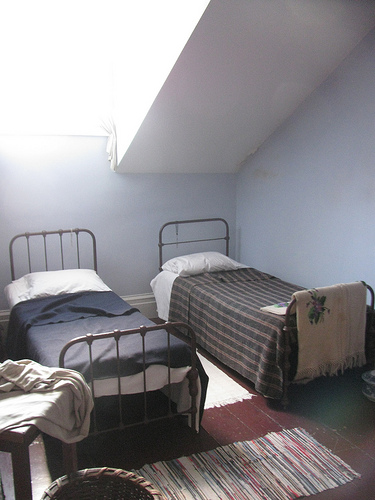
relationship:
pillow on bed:
[160, 250, 239, 275] [148, 218, 374, 412]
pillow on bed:
[12, 268, 110, 302] [148, 218, 374, 412]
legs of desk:
[4, 427, 63, 499] [0, 362, 76, 497]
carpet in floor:
[128, 426, 362, 500] [234, 400, 361, 450]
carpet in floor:
[128, 426, 362, 500] [207, 389, 374, 498]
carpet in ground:
[128, 426, 362, 500] [290, 400, 371, 463]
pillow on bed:
[12, 268, 110, 302] [8, 229, 198, 435]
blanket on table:
[0, 358, 94, 445] [2, 364, 90, 467]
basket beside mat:
[34, 461, 165, 499] [116, 423, 361, 495]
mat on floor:
[129, 426, 361, 498] [82, 361, 370, 498]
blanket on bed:
[260, 280, 367, 384] [147, 212, 372, 389]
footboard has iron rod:
[55, 309, 203, 419] [81, 339, 100, 437]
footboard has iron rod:
[55, 309, 203, 419] [108, 332, 125, 428]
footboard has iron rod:
[55, 309, 203, 419] [134, 325, 151, 424]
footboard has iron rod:
[55, 309, 203, 419] [158, 327, 176, 420]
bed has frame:
[148, 218, 374, 412] [159, 216, 228, 269]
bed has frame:
[5, 268, 195, 391] [9, 226, 97, 267]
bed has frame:
[148, 218, 374, 412] [155, 216, 230, 259]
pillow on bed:
[12, 263, 107, 298] [3, 262, 215, 379]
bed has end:
[148, 218, 374, 412] [277, 278, 373, 411]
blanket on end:
[286, 278, 372, 388] [277, 278, 373, 411]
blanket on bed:
[286, 278, 372, 388] [148, 218, 374, 412]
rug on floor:
[195, 349, 253, 410] [78, 316, 372, 498]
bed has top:
[8, 229, 198, 435] [7, 226, 99, 282]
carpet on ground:
[118, 419, 373, 498] [0, 373, 370, 497]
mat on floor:
[125, 415, 370, 496] [132, 361, 373, 498]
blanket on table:
[15, 343, 110, 449] [0, 378, 81, 498]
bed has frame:
[8, 229, 198, 435] [57, 370, 200, 435]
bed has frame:
[148, 218, 374, 412] [278, 340, 373, 404]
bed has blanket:
[8, 229, 198, 435] [6, 289, 209, 433]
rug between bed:
[195, 349, 258, 410] [148, 218, 374, 412]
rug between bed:
[195, 349, 258, 410] [9, 212, 228, 465]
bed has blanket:
[148, 218, 374, 412] [153, 251, 370, 394]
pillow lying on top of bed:
[160, 251, 240, 278] [148, 218, 374, 412]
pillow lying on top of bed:
[12, 268, 110, 302] [0, 226, 210, 470]